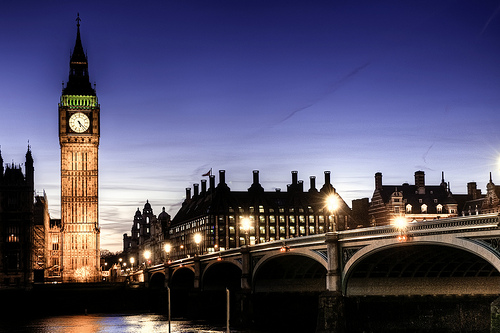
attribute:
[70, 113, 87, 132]
clock — black and white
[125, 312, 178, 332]
reflection — of the lights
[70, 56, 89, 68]
lights — neon green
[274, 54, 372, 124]
airplane trail — faint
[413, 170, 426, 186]
chimney — brick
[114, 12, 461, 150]
sky — dark blue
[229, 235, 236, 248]
window — lit up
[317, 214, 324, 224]
window — lit up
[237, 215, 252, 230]
window — lit up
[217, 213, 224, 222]
window — lit up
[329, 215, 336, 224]
window — lit up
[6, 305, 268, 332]
water — calm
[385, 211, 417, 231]
light — bright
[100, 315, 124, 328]
blue light — blue 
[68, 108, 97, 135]
clock — giant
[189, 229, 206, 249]
globe light — white 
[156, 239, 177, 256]
globe light — white 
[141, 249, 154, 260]
globe light — white 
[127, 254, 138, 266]
globe light — white 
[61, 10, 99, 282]
tower — lit